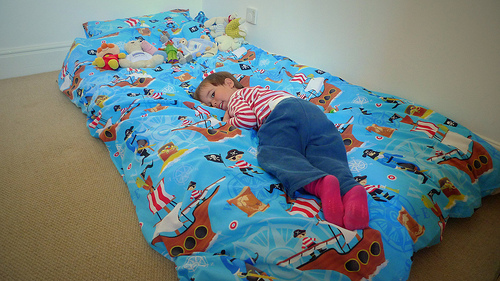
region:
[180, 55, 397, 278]
Child on the bed.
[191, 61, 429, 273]
Child lying on the bed.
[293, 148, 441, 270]
Pink socks on the child.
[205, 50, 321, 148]
Striped shirt on the child.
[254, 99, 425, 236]
pants on the child.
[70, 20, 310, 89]
Stuffed animals on the bed.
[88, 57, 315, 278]
pattern on the comforter.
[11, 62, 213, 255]
Carpet by the bed.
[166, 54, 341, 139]
Child looking at the camera.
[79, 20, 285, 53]
Pillow on the bed.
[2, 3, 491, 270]
a child is lying on a bed in a bedroom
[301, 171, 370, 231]
red socks are on the boy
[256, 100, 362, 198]
blue fleece pajamas are on the boy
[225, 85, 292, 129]
a red and white striped shirt is on the boy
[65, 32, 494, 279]
the bedspread is blue on the bed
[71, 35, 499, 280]
the bedspread has a pirate theme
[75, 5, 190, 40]
the pillow has a pirate theme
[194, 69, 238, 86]
the boy has brown hair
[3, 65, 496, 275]
a beige carpet is on the floor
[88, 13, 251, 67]
stuffed animals are at the head of the bed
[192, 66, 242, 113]
head of a person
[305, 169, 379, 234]
feet of a person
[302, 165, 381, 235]
socks of a person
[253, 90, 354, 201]
pants of a person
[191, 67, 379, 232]
person laying down on bed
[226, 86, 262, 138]
elbow of a person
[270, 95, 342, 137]
butt of a person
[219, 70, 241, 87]
ear of a person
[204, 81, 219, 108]
eyes of a person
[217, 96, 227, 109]
mouth of a person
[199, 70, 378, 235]
child laying on bed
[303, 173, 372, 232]
pink socks on child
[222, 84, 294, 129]
red and white striped shirt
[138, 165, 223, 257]
pirate ship design on bed cover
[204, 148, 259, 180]
pirate design on bed cover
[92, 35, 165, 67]
stuffed toys on bed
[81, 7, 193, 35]
bed pillow with cover matching bed cover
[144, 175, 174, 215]
red and white sail on sailboat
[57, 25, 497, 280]
bed cover with pirate designs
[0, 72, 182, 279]
tan carpet on floor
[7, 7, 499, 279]
Interior shot, season, unclear.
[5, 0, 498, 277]
Interior, bedroom of home, with person.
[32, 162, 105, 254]
Beige, carpeting, on floor.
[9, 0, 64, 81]
White wall and baseboard.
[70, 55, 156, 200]
Blue comforter, covering mattress.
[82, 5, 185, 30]
Top of pillow, seen, above tip of comforter.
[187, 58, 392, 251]
Resting child in blue pants, striped shirt and pink socks.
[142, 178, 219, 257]
Pirate ship, repeated as design on comforter.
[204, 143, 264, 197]
Pirate figure, detail on comforter.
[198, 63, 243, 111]
Boy's blonde head, smiling at picture-taker.